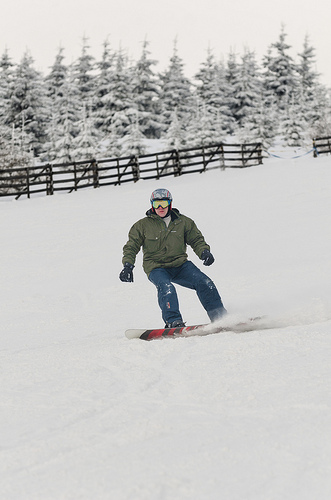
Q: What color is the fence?
A: Dark brown.